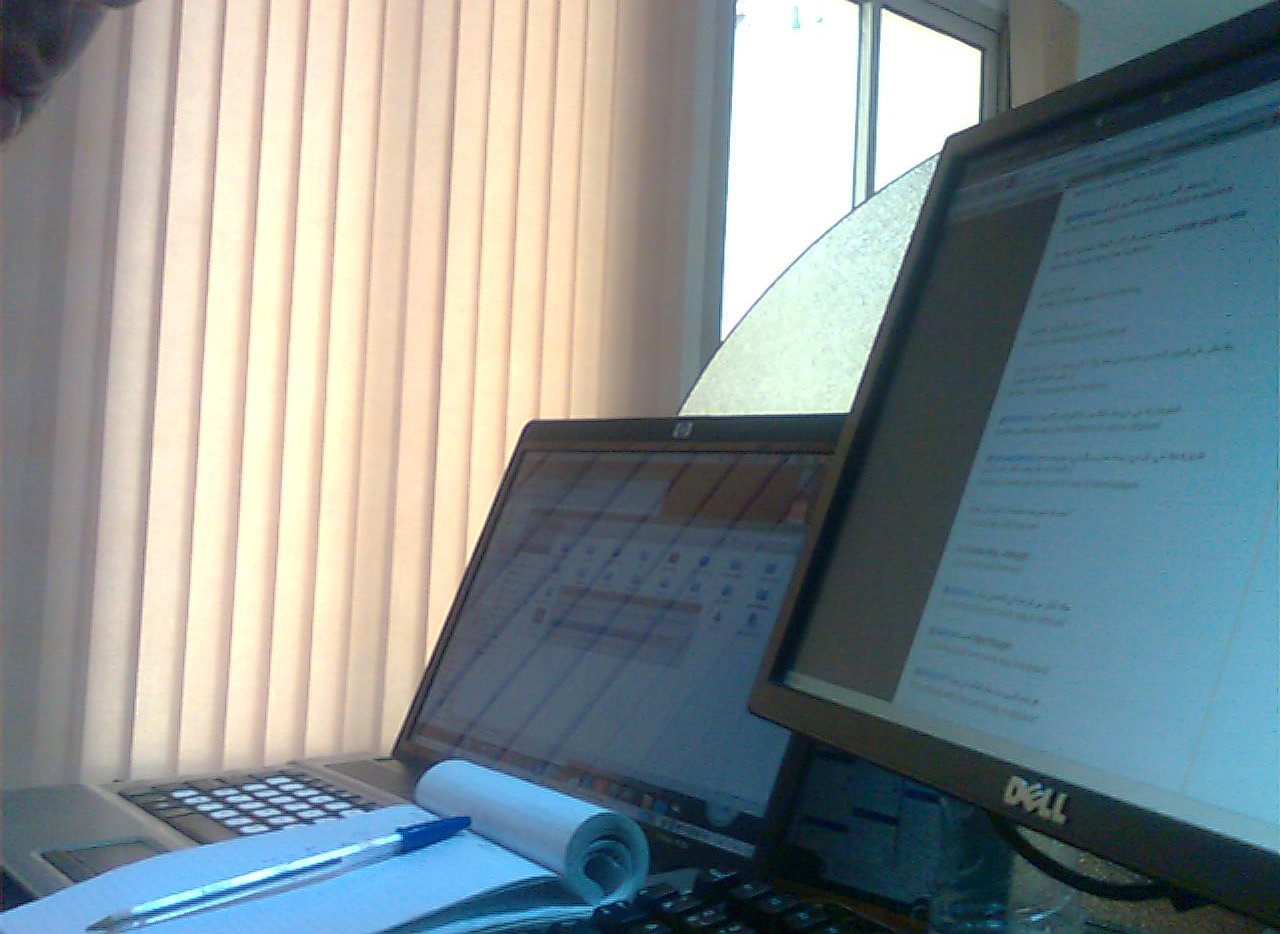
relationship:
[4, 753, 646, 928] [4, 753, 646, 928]
notepad of notepad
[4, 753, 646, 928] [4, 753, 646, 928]
notepad with notepad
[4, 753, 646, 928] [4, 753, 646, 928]
notepad resting on notepad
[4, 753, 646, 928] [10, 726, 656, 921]
notepad of paper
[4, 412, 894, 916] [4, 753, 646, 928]
hp laptop with notepad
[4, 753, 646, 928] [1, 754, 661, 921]
notepad of paper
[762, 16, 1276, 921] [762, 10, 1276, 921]
computer monitor using computer monitor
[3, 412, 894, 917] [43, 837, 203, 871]
hp laptop with touchpad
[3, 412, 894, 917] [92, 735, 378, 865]
hp laptop with keyboard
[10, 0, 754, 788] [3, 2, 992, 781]
blinds in front of sliding door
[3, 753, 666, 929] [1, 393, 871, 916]
notepad on laptop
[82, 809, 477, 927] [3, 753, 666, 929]
pen on notepad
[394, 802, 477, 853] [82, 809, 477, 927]
cap on pen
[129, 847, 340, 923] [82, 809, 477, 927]
ink on pen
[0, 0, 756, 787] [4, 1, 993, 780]
blinds on sliding door